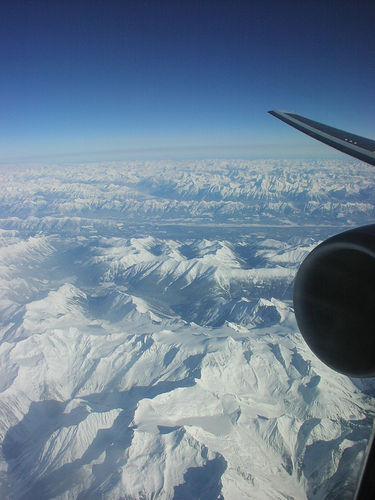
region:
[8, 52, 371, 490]
the view from a plane window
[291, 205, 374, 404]
a jet engine of a plane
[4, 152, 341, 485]
a view of several mountain tops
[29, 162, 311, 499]
several white mountain tops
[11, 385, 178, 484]
a shadow cast by a mountain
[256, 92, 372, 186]
part of the wing of a plane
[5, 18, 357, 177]
a dark and light blue sky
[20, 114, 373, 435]
a view from above the mountains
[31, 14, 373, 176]
no clouds in the sky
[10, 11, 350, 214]
a cloudless blue sky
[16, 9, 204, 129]
clear blue cloudless sky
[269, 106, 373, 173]
metal wing of aircraft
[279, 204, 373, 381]
large jet engine on aircraft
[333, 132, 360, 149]
three white dots on wing of aircraft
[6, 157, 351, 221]
snow covered mountain tops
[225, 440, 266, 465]
mountains covered in snow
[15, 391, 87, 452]
large shadows being cast on mountains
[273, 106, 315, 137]
white stripe on wing of aircraft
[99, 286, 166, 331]
large snow covered mountain top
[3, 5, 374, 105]
bright blue cloudless sky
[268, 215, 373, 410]
plane engine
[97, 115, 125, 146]
white clouds in blue sky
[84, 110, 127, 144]
white clouds in blue sky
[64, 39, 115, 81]
white clouds in blue sky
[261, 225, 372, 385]
A round jet engine.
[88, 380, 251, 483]
A birds eye view of a mountain peak.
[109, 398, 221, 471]
The mountain peak is white.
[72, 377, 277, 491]
The mountain peak is covered with snow.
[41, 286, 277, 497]
The mountain is jagged and rocky.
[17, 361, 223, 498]
The jet casts a shadow over the mountain.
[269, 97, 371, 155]
The wing of the jet can be seen.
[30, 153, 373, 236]
More mountains in the distance.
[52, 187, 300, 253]
The mountains have a crevasse between them.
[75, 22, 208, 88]
The sky is bright blue here.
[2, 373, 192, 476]
dark shadows on top of mountains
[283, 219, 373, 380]
engine on side of plane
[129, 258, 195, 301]
dip in mountain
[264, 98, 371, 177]
wing of airplane in sky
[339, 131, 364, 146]
three circular white marks on plane wing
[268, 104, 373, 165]
light grey stripe on plane wing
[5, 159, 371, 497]
sky view of mountains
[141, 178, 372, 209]
long shadow on mountains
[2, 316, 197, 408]
snow covered mountain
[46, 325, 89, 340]
top edge of mountain edge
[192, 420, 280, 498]
snow on the mountain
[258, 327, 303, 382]
snow on the mountain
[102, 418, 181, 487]
snow on the mountain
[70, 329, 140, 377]
snow on the mountain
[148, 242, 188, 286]
snow on the mountain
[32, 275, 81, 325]
snow on the mountain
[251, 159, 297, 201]
snow on the mountain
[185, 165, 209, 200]
snow on the mountain